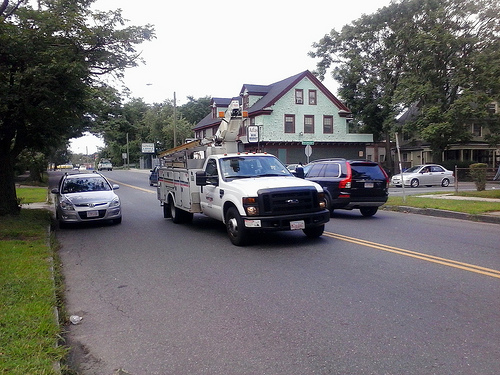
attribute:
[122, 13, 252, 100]
sky — white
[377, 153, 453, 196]
car — silver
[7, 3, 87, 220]
tree — tall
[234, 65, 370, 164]
house — light green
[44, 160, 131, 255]
car — silver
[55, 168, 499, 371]
street — gray, asphalt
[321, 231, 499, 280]
line — yellow, double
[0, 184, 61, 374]
grass — short, green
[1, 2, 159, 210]
tree — green, leafy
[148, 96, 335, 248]
truck — utility vehicle, white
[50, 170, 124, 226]
car — silver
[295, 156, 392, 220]
suv — black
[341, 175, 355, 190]
tail light — red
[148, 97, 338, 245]
utility truck — white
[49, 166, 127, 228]
car — silver